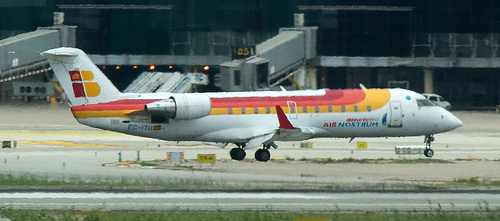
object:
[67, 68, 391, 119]
decorations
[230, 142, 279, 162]
back wheels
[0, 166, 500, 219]
ground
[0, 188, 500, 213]
road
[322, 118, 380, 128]
air nostrom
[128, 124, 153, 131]
license plate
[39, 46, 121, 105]
tail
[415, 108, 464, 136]
nose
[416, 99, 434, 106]
windows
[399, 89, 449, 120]
cockpit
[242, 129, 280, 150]
wing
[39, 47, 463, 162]
airplane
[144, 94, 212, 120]
engine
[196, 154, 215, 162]
sign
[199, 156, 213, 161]
black lettering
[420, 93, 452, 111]
car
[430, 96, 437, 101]
dark windows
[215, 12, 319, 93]
boarding tunnel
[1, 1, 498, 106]
building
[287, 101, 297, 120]
emergency door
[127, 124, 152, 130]
ec-itu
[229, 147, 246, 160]
wheels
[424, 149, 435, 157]
front wheel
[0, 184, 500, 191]
edge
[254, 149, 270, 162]
wheel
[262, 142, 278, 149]
landing gear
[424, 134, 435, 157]
front landing gear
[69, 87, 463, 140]
fuselage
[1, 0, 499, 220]
picture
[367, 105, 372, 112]
window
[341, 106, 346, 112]
window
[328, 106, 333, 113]
window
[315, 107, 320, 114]
window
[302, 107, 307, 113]
window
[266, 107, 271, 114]
window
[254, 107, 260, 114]
window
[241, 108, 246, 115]
window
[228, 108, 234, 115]
window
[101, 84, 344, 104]
red stripe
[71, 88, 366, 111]
orange stripe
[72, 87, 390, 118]
yellow stripe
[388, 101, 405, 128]
door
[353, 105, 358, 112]
windows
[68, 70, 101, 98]
logo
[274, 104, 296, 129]
wing tip